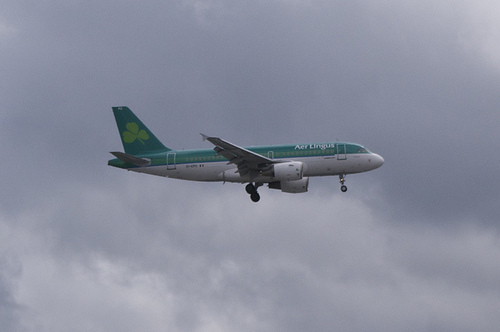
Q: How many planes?
A: 1.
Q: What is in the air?
A: Plane.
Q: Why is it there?
A: Traveling.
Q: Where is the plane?
A: In the air.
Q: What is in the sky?
A: Clouds.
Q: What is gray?
A: The sky.